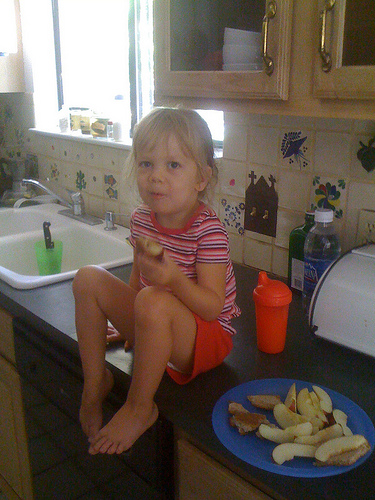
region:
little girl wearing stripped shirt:
[57, 81, 231, 457]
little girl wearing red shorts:
[62, 94, 237, 465]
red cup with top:
[251, 261, 304, 358]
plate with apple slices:
[215, 361, 365, 489]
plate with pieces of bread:
[201, 350, 369, 486]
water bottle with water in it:
[293, 193, 328, 326]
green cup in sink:
[31, 219, 70, 269]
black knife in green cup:
[32, 215, 64, 270]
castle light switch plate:
[235, 155, 282, 243]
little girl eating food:
[66, 94, 224, 466]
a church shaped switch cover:
[243, 166, 284, 238]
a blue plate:
[206, 374, 362, 491]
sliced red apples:
[229, 386, 367, 469]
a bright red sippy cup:
[249, 269, 291, 356]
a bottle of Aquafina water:
[302, 207, 337, 310]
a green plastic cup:
[33, 233, 64, 281]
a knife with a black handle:
[38, 218, 57, 277]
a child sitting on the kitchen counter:
[71, 107, 237, 462]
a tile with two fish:
[102, 171, 121, 201]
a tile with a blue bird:
[280, 128, 311, 171]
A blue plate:
[191, 417, 296, 496]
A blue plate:
[218, 374, 266, 497]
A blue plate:
[227, 398, 280, 482]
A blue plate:
[220, 442, 255, 493]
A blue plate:
[184, 365, 274, 455]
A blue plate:
[213, 390, 253, 443]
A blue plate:
[245, 368, 291, 471]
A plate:
[214, 401, 289, 499]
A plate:
[230, 405, 278, 481]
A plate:
[190, 394, 319, 472]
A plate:
[209, 355, 336, 495]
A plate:
[201, 355, 274, 470]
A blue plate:
[221, 371, 344, 493]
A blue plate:
[218, 394, 310, 468]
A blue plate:
[241, 397, 305, 428]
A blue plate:
[260, 382, 324, 439]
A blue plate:
[218, 406, 260, 463]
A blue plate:
[224, 436, 278, 498]